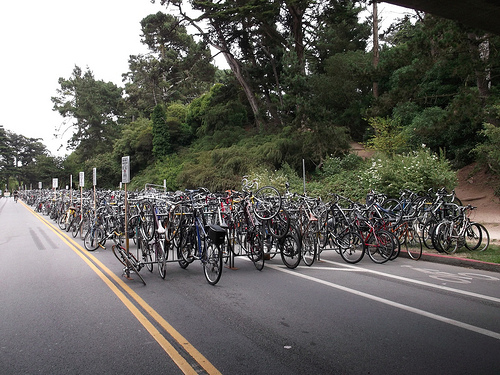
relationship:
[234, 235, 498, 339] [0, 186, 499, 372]
lines on street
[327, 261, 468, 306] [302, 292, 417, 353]
white lines on road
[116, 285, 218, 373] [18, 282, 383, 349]
lines on road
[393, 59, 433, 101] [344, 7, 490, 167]
leaves on trees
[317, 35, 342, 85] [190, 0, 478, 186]
leaves on trees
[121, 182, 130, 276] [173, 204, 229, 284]
post next to bike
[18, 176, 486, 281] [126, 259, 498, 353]
bicycles are on road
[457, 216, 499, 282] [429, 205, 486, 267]
tire on bicycle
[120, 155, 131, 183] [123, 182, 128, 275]
sign on pole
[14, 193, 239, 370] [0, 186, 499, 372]
lines on street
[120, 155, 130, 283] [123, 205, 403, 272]
sign on bike rack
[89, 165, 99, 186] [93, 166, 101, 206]
sign on pole